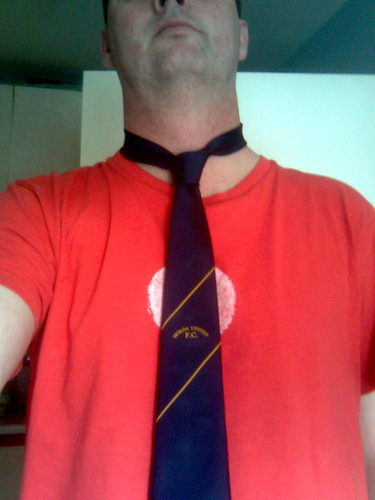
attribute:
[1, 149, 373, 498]
t-shirt — orange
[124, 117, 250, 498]
necktie — blue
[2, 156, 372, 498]
shirt — red, collared, Orange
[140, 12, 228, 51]
mouth — closed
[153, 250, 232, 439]
stripes — gold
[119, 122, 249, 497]
blue/gold tie — blue, gold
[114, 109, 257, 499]
tie — Purple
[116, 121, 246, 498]
tie — Purple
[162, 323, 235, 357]
logo — on he neck tie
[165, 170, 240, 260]
necktie — blue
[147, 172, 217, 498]
tie — neck, navy, blue